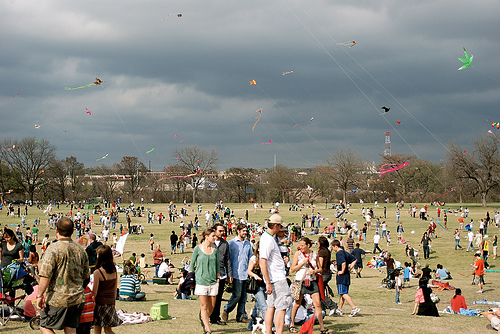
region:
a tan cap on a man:
[266, 213, 289, 228]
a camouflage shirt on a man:
[33, 239, 88, 309]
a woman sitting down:
[116, 267, 144, 302]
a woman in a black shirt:
[0, 225, 20, 275]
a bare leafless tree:
[447, 125, 497, 207]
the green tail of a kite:
[62, 80, 92, 90]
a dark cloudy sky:
[0, 2, 497, 182]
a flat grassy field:
[4, 201, 495, 331]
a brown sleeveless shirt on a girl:
[90, 265, 120, 306]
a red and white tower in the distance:
[378, 125, 394, 168]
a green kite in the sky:
[451, 46, 480, 73]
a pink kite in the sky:
[365, 157, 409, 178]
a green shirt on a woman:
[190, 244, 224, 282]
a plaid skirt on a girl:
[92, 304, 125, 325]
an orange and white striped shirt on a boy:
[78, 283, 94, 325]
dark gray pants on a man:
[36, 294, 88, 327]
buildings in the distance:
[69, 166, 341, 195]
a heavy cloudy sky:
[8, 2, 495, 173]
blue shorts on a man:
[334, 278, 350, 295]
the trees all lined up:
[1, 138, 498, 207]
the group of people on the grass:
[5, 203, 495, 329]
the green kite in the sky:
[457, 47, 473, 74]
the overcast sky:
[11, 7, 497, 141]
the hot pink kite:
[377, 161, 404, 174]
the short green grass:
[362, 295, 391, 332]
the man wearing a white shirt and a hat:
[264, 214, 290, 332]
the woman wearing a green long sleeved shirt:
[190, 229, 219, 331]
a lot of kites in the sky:
[24, 11, 497, 127]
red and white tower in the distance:
[383, 129, 393, 161]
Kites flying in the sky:
[1, 1, 497, 176]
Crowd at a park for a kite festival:
[1, 200, 497, 326]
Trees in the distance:
[3, 140, 496, 200]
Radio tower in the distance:
[375, 120, 398, 160]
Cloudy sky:
[0, 0, 496, 150]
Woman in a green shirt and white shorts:
[187, 226, 225, 329]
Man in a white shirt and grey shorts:
[257, 210, 293, 330]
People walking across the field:
[190, 220, 250, 331]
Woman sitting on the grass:
[412, 273, 442, 314]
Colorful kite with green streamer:
[58, 73, 105, 98]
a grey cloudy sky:
[59, 20, 370, 155]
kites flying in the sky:
[248, 47, 376, 135]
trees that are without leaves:
[2, 139, 107, 196]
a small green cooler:
[136, 297, 186, 324]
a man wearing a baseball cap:
[254, 211, 300, 322]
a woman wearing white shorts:
[190, 239, 225, 307]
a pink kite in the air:
[377, 140, 415, 183]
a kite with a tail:
[51, 70, 106, 97]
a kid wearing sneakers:
[323, 236, 370, 332]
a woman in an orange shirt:
[448, 285, 493, 320]